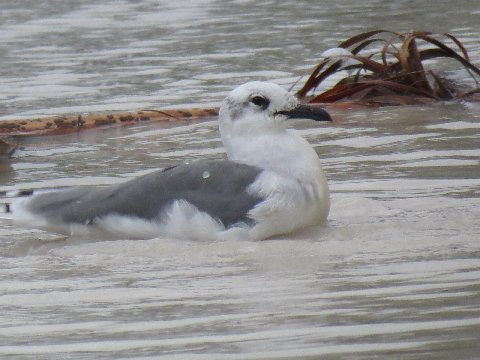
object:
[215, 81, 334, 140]
head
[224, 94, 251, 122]
markings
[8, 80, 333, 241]
bird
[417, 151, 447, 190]
ground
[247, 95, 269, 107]
eye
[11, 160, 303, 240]
feathers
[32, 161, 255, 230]
grey wing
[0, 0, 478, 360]
water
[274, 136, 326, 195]
chest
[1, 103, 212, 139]
tree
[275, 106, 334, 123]
beak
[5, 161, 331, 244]
body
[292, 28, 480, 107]
plants